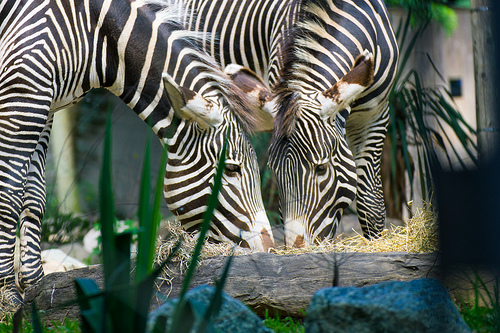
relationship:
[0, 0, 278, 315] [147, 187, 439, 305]
zebra eating hay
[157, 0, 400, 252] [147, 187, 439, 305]
zebra eating hay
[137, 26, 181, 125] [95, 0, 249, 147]
stripe on top of neck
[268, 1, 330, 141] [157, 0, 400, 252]
mane of zebra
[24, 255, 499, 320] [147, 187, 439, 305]
rock in front of hay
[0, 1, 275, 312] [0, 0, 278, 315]
fur of zebra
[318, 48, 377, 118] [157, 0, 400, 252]
ear of a zebra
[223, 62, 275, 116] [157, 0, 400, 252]
ear of a zebra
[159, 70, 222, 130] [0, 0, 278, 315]
ear of a zebra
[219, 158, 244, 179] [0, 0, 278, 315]
eye of a zebra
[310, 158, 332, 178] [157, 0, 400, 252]
eye of a zebra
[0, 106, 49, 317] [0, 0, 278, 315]
leg of a zebra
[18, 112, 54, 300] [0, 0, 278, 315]
leg of a zebra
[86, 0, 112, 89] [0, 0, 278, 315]
stripe of a zebra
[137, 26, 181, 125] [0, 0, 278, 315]
stripe of a zebra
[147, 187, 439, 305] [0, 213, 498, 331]
hay on top of ground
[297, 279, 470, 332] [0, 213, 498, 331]
rock on top of ground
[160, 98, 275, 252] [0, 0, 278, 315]
head of a zebra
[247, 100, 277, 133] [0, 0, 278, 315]
ear of a zebra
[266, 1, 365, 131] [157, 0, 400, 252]
neck of a zebra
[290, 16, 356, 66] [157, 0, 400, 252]
stripe of a zebra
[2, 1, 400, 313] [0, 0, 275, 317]
couple of zebra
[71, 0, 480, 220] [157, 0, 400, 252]
wall behind zebra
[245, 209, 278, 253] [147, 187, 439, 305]
nose inside of hay